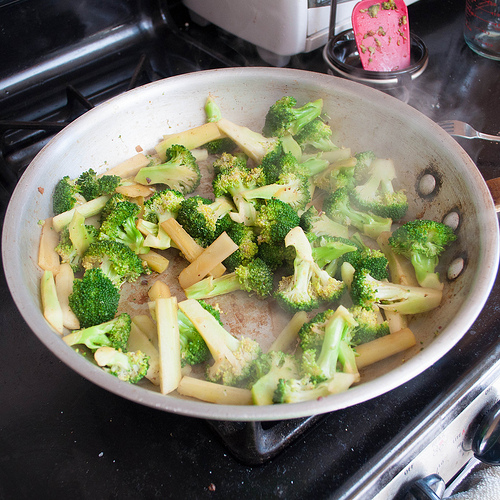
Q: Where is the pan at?
A: Over stove.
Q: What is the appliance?
A: Stove in kitchen.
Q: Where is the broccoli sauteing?
A: In pan.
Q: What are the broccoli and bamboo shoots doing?
A: Cooking.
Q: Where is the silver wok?
A: Stove.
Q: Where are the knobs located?
A: Front of stove.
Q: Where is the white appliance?
A: Counter.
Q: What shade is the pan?
A: Silver.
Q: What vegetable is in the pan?
A: Broccoli.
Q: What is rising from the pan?
A: Steam.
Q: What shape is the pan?
A: Round.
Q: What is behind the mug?
A: White toaster.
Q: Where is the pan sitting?
A: On the stove.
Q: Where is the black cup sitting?
A: On the counter.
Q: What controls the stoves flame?
A: Knobs.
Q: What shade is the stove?
A: Black.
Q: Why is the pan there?
A: It's cooking.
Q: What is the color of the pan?
A: Silver.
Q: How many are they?
A: 1.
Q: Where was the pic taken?
A: In the kitchen.